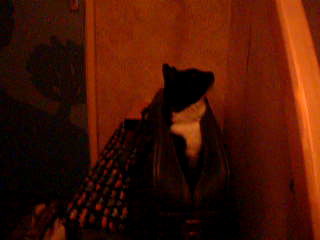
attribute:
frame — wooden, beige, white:
[81, 0, 94, 170]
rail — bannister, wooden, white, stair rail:
[268, 0, 320, 240]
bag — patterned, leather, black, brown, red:
[128, 84, 233, 238]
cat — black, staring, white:
[161, 62, 216, 168]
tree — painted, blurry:
[24, 34, 88, 122]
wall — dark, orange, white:
[0, 0, 87, 138]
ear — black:
[162, 62, 175, 81]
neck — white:
[165, 95, 207, 123]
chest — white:
[167, 120, 203, 164]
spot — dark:
[1, 0, 16, 50]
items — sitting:
[22, 201, 87, 232]